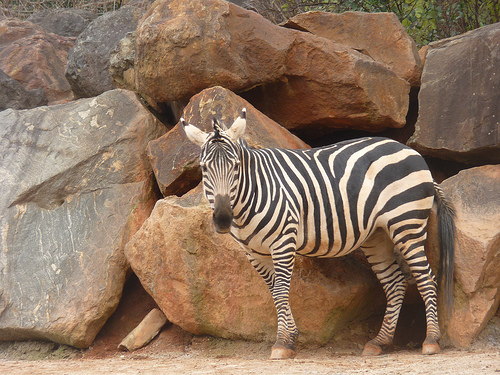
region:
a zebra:
[198, 129, 411, 286]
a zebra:
[243, 132, 348, 243]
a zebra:
[261, 131, 303, 216]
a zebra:
[235, 137, 285, 222]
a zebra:
[241, 120, 333, 331]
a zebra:
[203, 173, 304, 322]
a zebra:
[273, 237, 306, 359]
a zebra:
[193, 148, 353, 359]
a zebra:
[278, 186, 380, 373]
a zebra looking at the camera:
[174, 100, 478, 361]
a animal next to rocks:
[15, 22, 489, 373]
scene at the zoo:
[5, 20, 495, 350]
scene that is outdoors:
[12, 18, 494, 373]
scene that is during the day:
[15, 10, 468, 363]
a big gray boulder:
[4, 88, 190, 347]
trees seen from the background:
[235, 0, 498, 60]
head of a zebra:
[167, 97, 269, 264]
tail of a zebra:
[422, 171, 473, 308]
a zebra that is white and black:
[167, 103, 489, 373]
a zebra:
[237, 144, 300, 284]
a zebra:
[243, 182, 291, 331]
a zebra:
[235, 159, 257, 209]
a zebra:
[283, 199, 337, 325]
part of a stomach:
[314, 171, 359, 221]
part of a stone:
[191, 268, 242, 344]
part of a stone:
[188, 247, 225, 297]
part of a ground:
[216, 343, 241, 358]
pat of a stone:
[200, 276, 252, 323]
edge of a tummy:
[316, 240, 362, 260]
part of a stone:
[108, 320, 148, 368]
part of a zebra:
[210, 192, 231, 214]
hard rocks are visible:
[42, 51, 202, 208]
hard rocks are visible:
[57, 55, 154, 183]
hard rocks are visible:
[82, 201, 217, 359]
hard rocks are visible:
[14, 25, 189, 153]